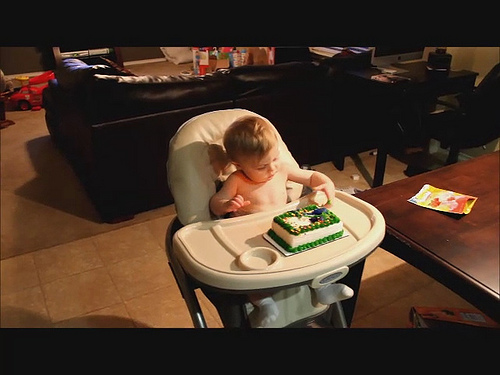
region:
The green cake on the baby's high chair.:
[272, 193, 342, 246]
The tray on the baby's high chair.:
[176, 187, 385, 277]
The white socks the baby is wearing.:
[260, 280, 357, 328]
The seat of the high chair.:
[169, 114, 306, 206]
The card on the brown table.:
[410, 182, 481, 222]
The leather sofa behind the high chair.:
[49, 51, 396, 181]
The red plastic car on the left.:
[7, 63, 52, 110]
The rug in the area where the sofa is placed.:
[4, 92, 96, 237]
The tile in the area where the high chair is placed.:
[9, 145, 450, 368]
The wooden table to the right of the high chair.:
[362, 165, 499, 302]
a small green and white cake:
[269, 201, 345, 251]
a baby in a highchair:
[166, 109, 385, 331]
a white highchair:
[166, 105, 386, 330]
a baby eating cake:
[211, 116, 355, 328]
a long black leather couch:
[40, 52, 354, 226]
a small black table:
[342, 60, 478, 185]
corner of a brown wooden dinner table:
[351, 148, 499, 324]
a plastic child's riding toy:
[10, 71, 63, 111]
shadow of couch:
[12, 130, 128, 234]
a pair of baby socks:
[259, 281, 354, 327]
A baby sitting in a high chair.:
[153, 87, 390, 341]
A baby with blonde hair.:
[201, 108, 303, 208]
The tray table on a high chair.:
[171, 190, 387, 290]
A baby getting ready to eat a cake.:
[178, 100, 361, 327]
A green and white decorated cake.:
[269, 196, 351, 253]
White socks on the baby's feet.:
[228, 280, 365, 323]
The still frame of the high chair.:
[157, 204, 359, 334]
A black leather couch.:
[30, 53, 401, 213]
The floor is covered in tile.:
[7, 48, 445, 321]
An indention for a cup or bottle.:
[226, 240, 287, 278]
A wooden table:
[342, 146, 498, 332]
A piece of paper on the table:
[409, 181, 475, 212]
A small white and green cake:
[270, 203, 341, 250]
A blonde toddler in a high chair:
[212, 118, 353, 310]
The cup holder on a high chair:
[239, 247, 278, 271]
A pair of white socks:
[247, 282, 352, 327]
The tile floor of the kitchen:
[3, 161, 498, 328]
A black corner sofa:
[37, 67, 364, 215]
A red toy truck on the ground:
[7, 85, 52, 111]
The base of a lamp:
[422, 40, 458, 71]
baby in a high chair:
[28, 70, 447, 324]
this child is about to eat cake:
[186, 129, 379, 319]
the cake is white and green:
[264, 207, 343, 258]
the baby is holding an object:
[310, 171, 359, 228]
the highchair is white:
[158, 126, 401, 331]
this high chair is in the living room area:
[93, 83, 451, 322]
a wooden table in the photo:
[385, 144, 493, 304]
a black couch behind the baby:
[47, 51, 384, 213]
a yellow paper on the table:
[409, 172, 488, 222]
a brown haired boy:
[211, 109, 289, 154]